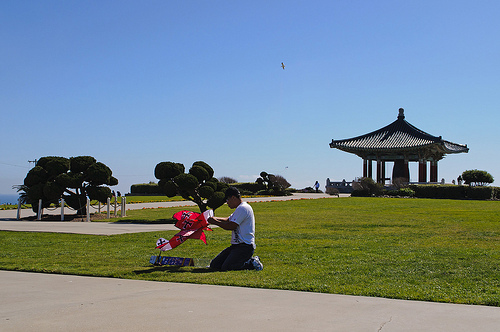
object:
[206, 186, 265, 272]
man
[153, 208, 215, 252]
kite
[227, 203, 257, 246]
t-shirt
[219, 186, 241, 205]
baseball cap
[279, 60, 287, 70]
bird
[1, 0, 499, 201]
sky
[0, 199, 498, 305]
grass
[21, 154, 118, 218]
bush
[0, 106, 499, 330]
park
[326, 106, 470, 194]
pagoda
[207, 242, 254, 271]
jeans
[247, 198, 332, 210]
plants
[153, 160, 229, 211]
tree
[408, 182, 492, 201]
bush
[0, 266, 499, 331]
sidewalk